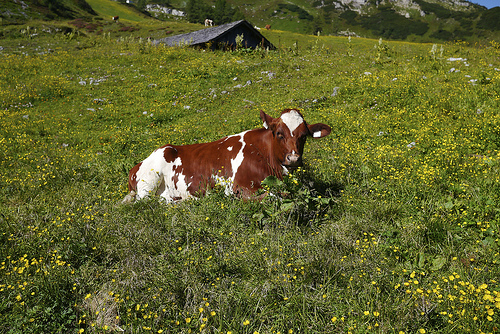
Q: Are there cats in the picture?
A: No, there are no cats.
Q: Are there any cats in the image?
A: No, there are no cats.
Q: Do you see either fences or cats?
A: No, there are no cats or fences.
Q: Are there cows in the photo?
A: Yes, there is a cow.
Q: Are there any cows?
A: Yes, there is a cow.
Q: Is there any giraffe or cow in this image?
A: Yes, there is a cow.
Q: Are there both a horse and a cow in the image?
A: No, there is a cow but no horses.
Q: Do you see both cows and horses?
A: No, there is a cow but no horses.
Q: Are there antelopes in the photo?
A: No, there are no antelopes.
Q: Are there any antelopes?
A: No, there are no antelopes.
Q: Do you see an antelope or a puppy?
A: No, there are no antelopes or puppies.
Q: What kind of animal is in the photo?
A: The animal is a cow.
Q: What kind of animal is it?
A: The animal is a cow.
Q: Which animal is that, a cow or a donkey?
A: That is a cow.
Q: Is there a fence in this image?
A: No, there are no fences.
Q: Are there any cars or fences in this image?
A: No, there are no fences or cars.